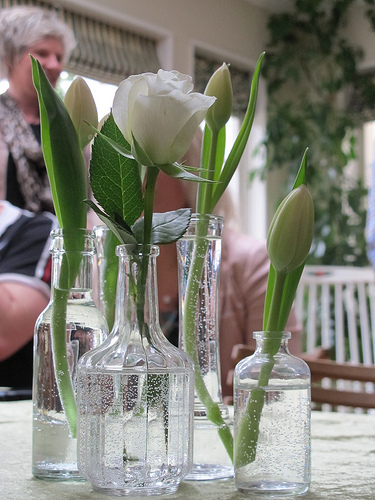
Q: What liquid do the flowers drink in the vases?
A: Water.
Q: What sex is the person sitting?
A: Female.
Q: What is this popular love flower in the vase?
A: Rose.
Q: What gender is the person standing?
A: Female.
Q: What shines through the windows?
A: Sunlight.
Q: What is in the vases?
A: Flowers.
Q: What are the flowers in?
A: Vases.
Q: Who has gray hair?
A: The woman.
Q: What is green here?
A: The stems.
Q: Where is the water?
A: In the vases.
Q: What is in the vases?
A: Water.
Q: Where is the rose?
A: In the vase.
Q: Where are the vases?
A: On a table.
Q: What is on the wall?
A: A vine.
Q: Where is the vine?
A: On the wall.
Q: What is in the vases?
A: Flowers.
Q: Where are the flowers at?
A: Vases.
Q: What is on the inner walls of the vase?
A: Bubbles.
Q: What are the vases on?
A: Table.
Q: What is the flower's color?
A: White.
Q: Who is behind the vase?
A: Some people.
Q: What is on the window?
A: Blinds.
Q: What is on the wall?
A: Plants.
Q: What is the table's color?
A: White.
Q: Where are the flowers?
A: In the vases.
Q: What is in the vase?
A: Flowers.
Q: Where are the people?
A: Behind the flowers.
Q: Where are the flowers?
A: In vases.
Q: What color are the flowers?
A: White.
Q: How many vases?
A: 4.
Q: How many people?
A: 3.